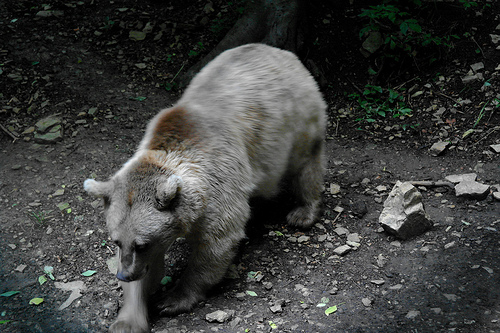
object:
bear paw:
[104, 304, 155, 332]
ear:
[150, 176, 179, 210]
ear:
[77, 177, 111, 199]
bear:
[78, 43, 329, 332]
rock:
[377, 180, 433, 240]